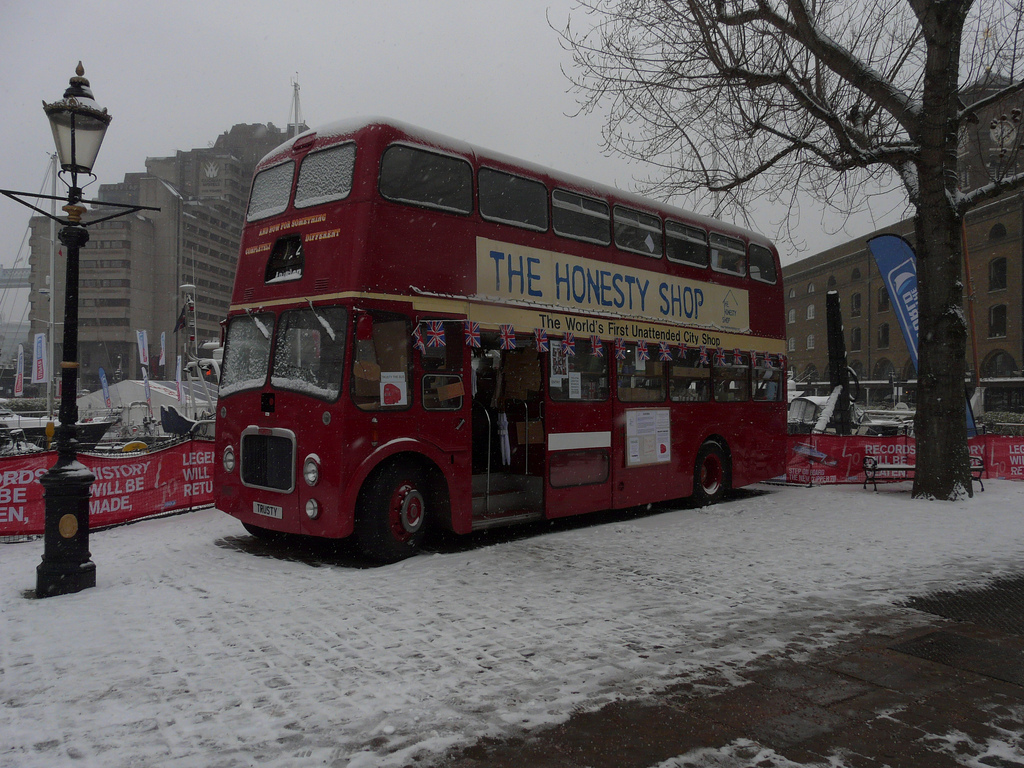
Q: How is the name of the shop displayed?
A: Banner sign.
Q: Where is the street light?
A: Front of bus.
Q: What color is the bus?
A: Red.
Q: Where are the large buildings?
A: Background.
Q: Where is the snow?
A: Ground.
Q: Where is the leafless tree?
A: Right side of photo.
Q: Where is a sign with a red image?
A: Window of the bus.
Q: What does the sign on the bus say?
A: The Honesty Shop.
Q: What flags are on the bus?
A: The Union Jack.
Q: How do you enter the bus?
A: Through the open door.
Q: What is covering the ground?
A: Snow.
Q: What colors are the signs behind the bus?
A: Red and white.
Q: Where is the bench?
A: Behind the tree.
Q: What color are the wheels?
A: Red with black tires.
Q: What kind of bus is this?
A: A double-decker.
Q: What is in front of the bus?
A: A vintage street lamp.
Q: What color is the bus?
A: Red.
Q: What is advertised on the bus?
A: The Honesty Shop.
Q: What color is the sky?
A: White.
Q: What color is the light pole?
A: Black.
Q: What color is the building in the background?
A: Brown.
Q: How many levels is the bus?
A: Two.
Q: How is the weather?
A: Overcast.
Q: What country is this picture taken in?
A: Great Britain.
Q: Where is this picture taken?
A: The street.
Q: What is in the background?
A: Buildings.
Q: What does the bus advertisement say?
A: The Honesty Shop.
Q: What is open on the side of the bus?
A: The doorway.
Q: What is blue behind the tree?
A: An advertisement sign.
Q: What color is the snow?
A: White.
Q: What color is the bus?
A: Red.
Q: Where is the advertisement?
A: On the side of the bus.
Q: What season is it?
A: Winter.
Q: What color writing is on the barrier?
A: White.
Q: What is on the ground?
A: Snow.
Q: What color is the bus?
A: Red.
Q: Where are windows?
A: On the bus.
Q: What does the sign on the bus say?
A: "THE HONESTY SHOP".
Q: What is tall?
A: A tree.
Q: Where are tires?
A: On the bus.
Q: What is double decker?
A: The bus.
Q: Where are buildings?
A: In the distance.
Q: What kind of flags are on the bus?
A: British flags.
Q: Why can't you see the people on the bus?
A: Not clearly visible.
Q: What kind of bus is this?
A: Double decker.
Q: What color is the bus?
A: Red.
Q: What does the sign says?
A: Honesty shop.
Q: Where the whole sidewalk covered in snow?
A: No partially.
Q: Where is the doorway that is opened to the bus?
A: By the side.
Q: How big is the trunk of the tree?
A: Large.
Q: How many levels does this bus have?
A: Two.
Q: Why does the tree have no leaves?
A: Winter.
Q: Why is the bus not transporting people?
A: It's a store.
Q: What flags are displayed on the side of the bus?
A: British.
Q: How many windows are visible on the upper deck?
A: Nine.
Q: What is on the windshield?
A: Snow.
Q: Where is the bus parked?
A: Sidewalk.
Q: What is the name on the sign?
A: The Honesty Shop.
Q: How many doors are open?
A: One.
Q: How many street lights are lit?
A: None.